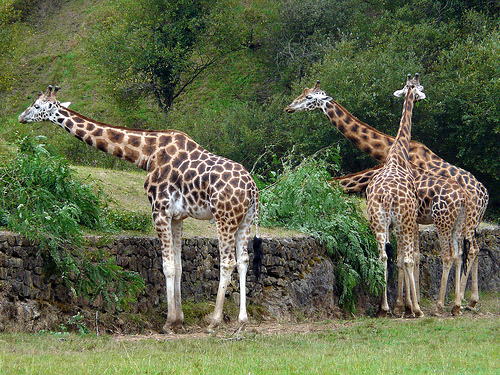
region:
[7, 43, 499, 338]
four giraffes by a stone wall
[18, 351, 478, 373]
green grasses by giraffes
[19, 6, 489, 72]
green trees near giraffes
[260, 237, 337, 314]
stone wall by the giraffes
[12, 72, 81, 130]
head of a giraffe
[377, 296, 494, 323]
hooves of three giraffes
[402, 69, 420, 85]
horns on a giraffe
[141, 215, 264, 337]
legs of a giraffe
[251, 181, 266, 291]
tail of a giraffe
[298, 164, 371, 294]
leaves from bushes on the ground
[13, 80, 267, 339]
Tall giraffe eating green foliage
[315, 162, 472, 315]
Giraffe partly hidden while eating green foliage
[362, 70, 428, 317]
Giraffe next to giraffe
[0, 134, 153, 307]
Green foliage dangling off wall of rocks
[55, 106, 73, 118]
Brown spot on neck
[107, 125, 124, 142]
Large brown spot by mane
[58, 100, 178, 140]
Mane running down neck of giraffe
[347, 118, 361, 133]
Spot is large and brown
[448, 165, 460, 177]
Spot is large and brown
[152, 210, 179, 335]
Leg is long with brown spots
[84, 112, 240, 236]
the giraffe has spots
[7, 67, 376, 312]
the giraffe has spots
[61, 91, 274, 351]
the giraffe has spots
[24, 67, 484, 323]
four giraffes standing behind wall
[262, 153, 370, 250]
green bush over wall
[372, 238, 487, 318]
legs of three giraffes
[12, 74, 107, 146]
giraffe looking to left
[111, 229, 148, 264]
top of stone wall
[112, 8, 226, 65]
green leaves on tree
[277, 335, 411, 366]
green grass on gound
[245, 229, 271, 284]
black hair on tail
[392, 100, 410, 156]
back of giraffe neck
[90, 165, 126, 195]
green grass on hill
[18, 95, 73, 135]
face of the giraffe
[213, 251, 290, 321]
legs of the zebra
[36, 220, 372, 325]
a hard stones before zebra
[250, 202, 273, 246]
tail of the zebra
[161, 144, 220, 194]
skin of the zebra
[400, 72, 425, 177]
long neck of the zebra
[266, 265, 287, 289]
small space in between stones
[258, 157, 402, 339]
a beautiful green tree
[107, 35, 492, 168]
a group of trees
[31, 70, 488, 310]
a group of giraffe